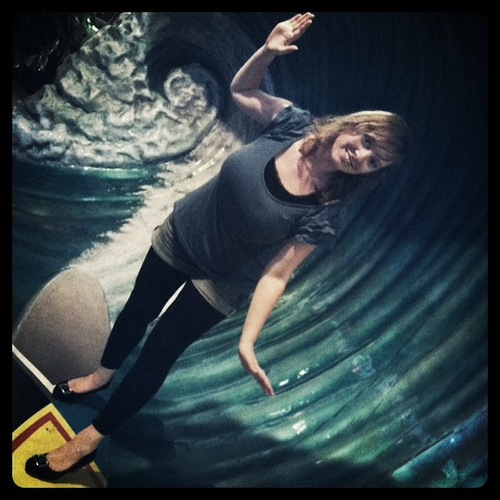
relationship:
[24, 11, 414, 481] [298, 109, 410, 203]
female has blonde hair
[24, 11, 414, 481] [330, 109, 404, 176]
female has head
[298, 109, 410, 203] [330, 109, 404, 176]
blonde hair on head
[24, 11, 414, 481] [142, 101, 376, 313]
female wearing shirt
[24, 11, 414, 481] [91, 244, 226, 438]
female wearing pants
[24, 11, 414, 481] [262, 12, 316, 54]
female has hand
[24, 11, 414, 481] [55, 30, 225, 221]
female surfing on water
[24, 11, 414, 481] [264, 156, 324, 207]
female wearing undershirt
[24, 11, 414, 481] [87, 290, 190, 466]
female wearing pants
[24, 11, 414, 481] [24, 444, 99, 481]
female wearing heels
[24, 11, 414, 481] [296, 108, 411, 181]
female has hair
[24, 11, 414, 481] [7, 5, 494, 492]
female posing for photo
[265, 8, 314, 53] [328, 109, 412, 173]
hand raised above head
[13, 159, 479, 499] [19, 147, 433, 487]
illusion on floor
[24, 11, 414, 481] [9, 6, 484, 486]
female in tube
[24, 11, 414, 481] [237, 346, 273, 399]
female with hand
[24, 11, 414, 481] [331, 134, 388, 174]
female with face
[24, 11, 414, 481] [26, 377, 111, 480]
female with feet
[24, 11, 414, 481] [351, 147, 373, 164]
female with nose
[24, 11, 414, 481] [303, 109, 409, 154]
female with blonde hair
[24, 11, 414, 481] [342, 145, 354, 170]
female with smile